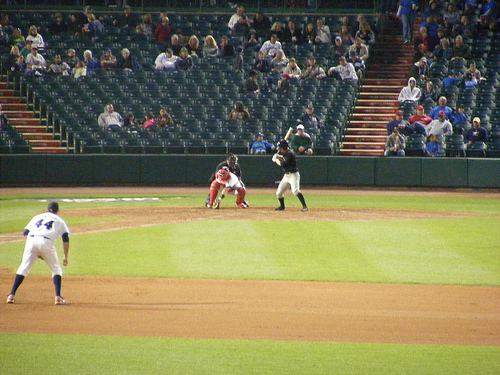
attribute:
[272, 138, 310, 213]
man — batter, playing baseball, batting, baseball player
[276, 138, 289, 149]
helmet — protective, black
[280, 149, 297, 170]
shirt — black, white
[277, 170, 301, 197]
pants — white, uniform pants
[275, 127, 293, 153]
baseball bat — wood, long, brown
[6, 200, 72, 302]
man — playing baseball, leaning forward, infielder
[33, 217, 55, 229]
number — 44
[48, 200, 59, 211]
cap — blue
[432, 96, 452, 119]
spectator — male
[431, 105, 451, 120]
shirt — blue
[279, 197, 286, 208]
sock — black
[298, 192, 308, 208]
sock — black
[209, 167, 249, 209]
catcher — playing baseball, squatting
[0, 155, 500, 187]
wall — low, green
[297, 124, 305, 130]
hat — white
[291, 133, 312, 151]
shirt — green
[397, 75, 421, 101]
hoodie — white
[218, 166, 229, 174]
baseball cap — red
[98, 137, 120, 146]
seat — blue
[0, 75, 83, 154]
stairs — red, white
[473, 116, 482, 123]
cap — yellow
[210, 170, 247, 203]
safety gear — red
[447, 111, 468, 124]
jacket — blue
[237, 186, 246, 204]
shinguard — red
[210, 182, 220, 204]
shinguard — red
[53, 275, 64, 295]
sock — blue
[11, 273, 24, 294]
sock — blue